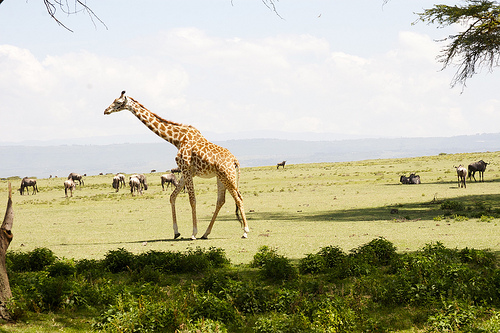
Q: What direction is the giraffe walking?
A: Left.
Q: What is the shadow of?
A: The tree.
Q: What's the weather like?
A: Partly cloudy and hot.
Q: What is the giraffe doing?
A: Walking.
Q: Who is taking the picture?
A: A photographer.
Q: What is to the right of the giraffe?
A: Green shrubs.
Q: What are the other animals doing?
A: Grazing.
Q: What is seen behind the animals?
A: Small foot hill.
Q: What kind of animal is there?
A: Giraffe.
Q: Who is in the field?
A: Animals.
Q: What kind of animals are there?
A: Wild animals.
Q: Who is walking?
A: The giraffe.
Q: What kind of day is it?
A: Hazy day.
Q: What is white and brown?
A: Giraffe.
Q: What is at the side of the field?
A: Small shrubs.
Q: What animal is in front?
A: A giraffe.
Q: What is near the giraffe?
A: Brush.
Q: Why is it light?
A: Daytime.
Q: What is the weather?
A: Cloudy.